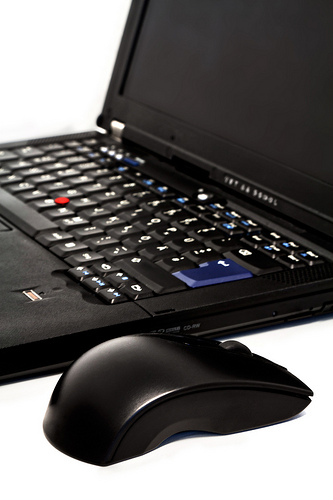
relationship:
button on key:
[173, 259, 251, 288] [0, 135, 326, 304]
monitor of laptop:
[95, 1, 330, 242] [0, 1, 333, 386]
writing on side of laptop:
[147, 320, 204, 332] [0, 1, 333, 386]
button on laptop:
[292, 241, 311, 264] [8, 6, 312, 376]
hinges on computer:
[106, 118, 127, 145] [0, 0, 333, 391]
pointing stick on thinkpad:
[54, 191, 67, 207] [22, 8, 332, 340]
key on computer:
[0, 135, 326, 304] [0, 0, 333, 391]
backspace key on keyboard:
[230, 246, 278, 280] [3, 119, 327, 351]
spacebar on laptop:
[7, 185, 59, 244] [0, 1, 333, 386]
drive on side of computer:
[164, 284, 322, 339] [0, 0, 333, 391]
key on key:
[0, 135, 326, 304] [0, 135, 326, 304]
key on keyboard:
[151, 257, 234, 278] [87, 182, 270, 298]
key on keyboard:
[0, 135, 326, 304] [1, 128, 332, 382]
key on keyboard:
[0, 135, 326, 304] [3, 119, 327, 351]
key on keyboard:
[0, 135, 326, 304] [0, 130, 332, 336]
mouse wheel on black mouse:
[219, 333, 254, 360] [39, 331, 312, 465]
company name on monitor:
[220, 171, 282, 209] [114, 3, 333, 192]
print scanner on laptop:
[17, 283, 43, 304] [120, 62, 290, 236]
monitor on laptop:
[114, 3, 333, 192] [0, 1, 333, 386]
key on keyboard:
[0, 135, 326, 304] [2, 131, 329, 307]